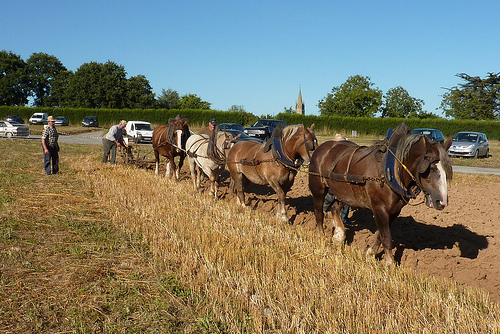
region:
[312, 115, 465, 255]
brown horse in the field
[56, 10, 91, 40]
white clouds in blue sky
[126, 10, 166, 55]
white clouds in blue sky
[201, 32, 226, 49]
white clouds in blue sky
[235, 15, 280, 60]
white clouds in blue sky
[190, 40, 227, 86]
white clouds in blue sky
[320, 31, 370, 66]
white clouds in blue sky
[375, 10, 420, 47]
white clouds in blue sky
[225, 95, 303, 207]
brown horse in the field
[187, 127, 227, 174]
brown horse in the field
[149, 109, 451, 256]
four horses in a line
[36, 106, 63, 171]
man standing in field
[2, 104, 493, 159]
cars parked around the field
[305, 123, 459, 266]
brown lead horse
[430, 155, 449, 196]
white marking on face of lead horse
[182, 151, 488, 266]
shadows of horses on the dirt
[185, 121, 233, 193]
white horse in the line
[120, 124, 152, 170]
plow hooked to horses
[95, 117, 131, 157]
man directing the plow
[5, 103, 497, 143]
row of hedges in the background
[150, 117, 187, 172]
the brown wide horse plowing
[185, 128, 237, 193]
the brown wide horse plowing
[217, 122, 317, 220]
the brown wide horse plowing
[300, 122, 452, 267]
the brown wide horse plowing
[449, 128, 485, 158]
the silver car parked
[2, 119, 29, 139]
the silver car parked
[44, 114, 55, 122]
the straw hat of the person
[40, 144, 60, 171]
the pair of blue jeans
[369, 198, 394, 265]
the brown leg of the horse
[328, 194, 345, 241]
the brown leg of the horse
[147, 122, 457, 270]
a team of horses in the field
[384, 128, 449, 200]
a yoke for a working horse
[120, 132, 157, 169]
a horse drawn plow in the field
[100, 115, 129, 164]
man who is standing to the side of a plow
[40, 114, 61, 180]
man in a tan cap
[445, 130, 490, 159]
car parked on the ground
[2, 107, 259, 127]
a long well-trimmed hedge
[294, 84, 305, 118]
the steeple of a church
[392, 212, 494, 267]
the shadow of the lead horse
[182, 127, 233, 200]
a white horse in the work team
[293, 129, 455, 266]
horse in a field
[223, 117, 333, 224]
horse in a field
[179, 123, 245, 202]
horse in a field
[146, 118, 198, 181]
horse in a field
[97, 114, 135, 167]
man in a field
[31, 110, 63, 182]
man in a field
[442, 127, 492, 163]
car parked in a field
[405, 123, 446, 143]
car parked in a field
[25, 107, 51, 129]
car parked in a field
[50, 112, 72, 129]
car parked in a field